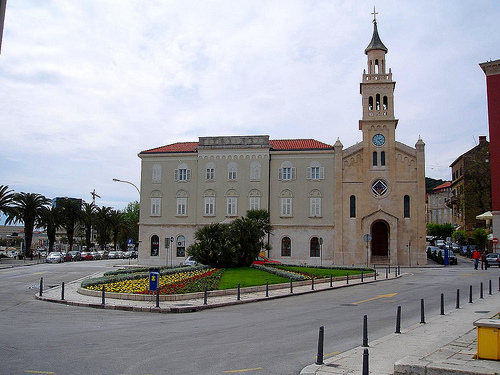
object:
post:
[155, 287, 160, 307]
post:
[101, 284, 105, 303]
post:
[61, 281, 64, 300]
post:
[39, 277, 43, 297]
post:
[204, 286, 208, 305]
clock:
[371, 132, 387, 148]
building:
[136, 6, 430, 266]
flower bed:
[80, 260, 374, 296]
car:
[437, 249, 457, 265]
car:
[46, 251, 65, 263]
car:
[60, 252, 73, 262]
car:
[67, 250, 81, 262]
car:
[80, 251, 93, 260]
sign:
[149, 272, 158, 290]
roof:
[137, 138, 335, 159]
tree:
[1, 191, 57, 257]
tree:
[34, 204, 68, 255]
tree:
[55, 197, 88, 252]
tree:
[76, 199, 103, 250]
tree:
[91, 205, 117, 250]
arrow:
[349, 292, 398, 304]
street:
[1, 245, 500, 374]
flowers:
[174, 280, 177, 283]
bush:
[184, 208, 275, 269]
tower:
[358, 5, 398, 267]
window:
[282, 167, 293, 180]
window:
[311, 166, 321, 180]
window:
[249, 166, 260, 180]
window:
[227, 166, 237, 180]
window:
[205, 167, 215, 180]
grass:
[218, 267, 295, 290]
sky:
[0, 0, 499, 227]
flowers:
[178, 284, 182, 287]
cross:
[371, 6, 379, 20]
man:
[471, 249, 481, 271]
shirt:
[472, 252, 482, 260]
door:
[371, 220, 389, 256]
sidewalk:
[0, 256, 46, 269]